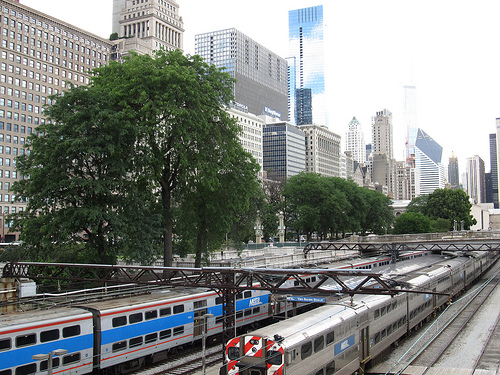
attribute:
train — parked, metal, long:
[226, 261, 465, 368]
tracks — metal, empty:
[442, 261, 497, 372]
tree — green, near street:
[45, 66, 260, 273]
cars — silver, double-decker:
[3, 285, 264, 366]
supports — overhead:
[12, 260, 389, 301]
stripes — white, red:
[225, 341, 295, 373]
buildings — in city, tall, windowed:
[40, 8, 419, 218]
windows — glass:
[9, 20, 113, 104]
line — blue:
[110, 290, 271, 346]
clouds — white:
[367, 22, 479, 71]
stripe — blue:
[99, 289, 269, 325]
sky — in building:
[288, 15, 320, 89]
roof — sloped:
[418, 124, 443, 160]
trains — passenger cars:
[7, 240, 469, 370]